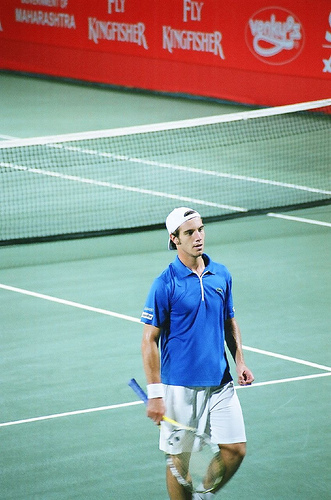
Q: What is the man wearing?
A: A blue shirt.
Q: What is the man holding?
A: Tennis racket.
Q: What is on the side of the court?
A: Red wall.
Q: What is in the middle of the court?
A: Net.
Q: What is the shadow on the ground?
A: Net.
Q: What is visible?
A: The white line.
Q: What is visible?
A: White line on the court.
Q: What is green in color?
A: The ground is.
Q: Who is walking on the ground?
A: The man is walking.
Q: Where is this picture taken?
A: A tennis court.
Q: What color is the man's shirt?
A: Blue.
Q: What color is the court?
A: Green.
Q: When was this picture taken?
A: Daytime.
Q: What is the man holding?
A: A racket.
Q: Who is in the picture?
A: A man.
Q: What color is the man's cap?
A: White.